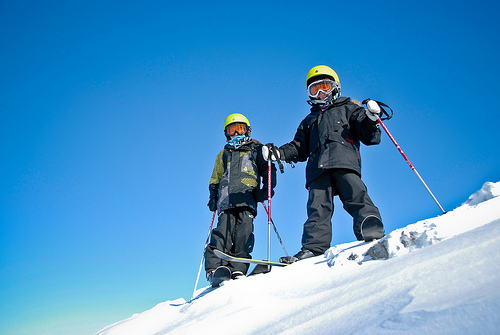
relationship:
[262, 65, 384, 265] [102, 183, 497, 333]
people on hill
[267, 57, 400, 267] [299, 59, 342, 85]
people wears helmet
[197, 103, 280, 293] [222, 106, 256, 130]
people wears helmet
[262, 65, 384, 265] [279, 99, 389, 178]
people wears jacket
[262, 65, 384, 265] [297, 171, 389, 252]
people wears pants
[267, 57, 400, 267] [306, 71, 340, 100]
people wears goggles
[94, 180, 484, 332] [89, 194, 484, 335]
snow covering ground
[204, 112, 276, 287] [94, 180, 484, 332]
people standing in snow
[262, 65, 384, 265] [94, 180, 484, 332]
people standing in snow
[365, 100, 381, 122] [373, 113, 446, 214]
glove placed on design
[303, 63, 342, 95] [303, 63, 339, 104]
helmet covering head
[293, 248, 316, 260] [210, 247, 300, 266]
boot standing on top of ski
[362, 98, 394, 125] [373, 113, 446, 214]
strap attached to design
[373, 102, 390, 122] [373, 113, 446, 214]
strap attached to design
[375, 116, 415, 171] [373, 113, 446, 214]
design adorning design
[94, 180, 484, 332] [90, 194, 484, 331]
snow covering ground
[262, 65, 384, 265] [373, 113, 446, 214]
people holding design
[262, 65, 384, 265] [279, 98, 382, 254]
people wearing snowsuit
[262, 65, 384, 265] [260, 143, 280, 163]
people wearing glove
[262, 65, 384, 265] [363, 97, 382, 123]
people wearing glove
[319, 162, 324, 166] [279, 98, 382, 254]
button sewn on snowsuit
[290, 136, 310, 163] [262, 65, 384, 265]
elbow belonging to people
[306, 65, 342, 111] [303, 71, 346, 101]
helmet by goggles